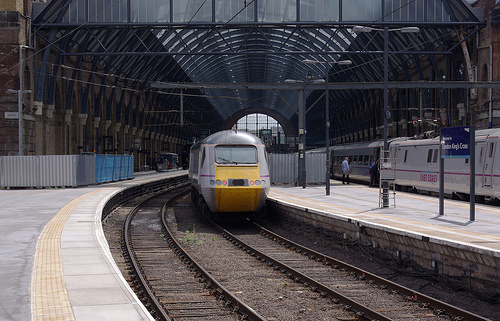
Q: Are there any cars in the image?
A: No, there are no cars.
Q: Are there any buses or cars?
A: No, there are no cars or buses.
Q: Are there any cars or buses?
A: No, there are no cars or buses.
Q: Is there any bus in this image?
A: No, there are no buses.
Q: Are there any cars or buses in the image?
A: No, there are no buses or cars.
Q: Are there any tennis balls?
A: No, there are no tennis balls.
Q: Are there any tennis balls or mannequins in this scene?
A: No, there are no tennis balls or mannequins.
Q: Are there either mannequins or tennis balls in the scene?
A: No, there are no tennis balls or mannequins.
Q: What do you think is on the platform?
A: The cable is on the platform.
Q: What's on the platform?
A: The cable is on the platform.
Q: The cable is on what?
A: The cable is on the platform.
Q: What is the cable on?
A: The cable is on the platform.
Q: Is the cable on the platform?
A: Yes, the cable is on the platform.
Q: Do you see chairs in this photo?
A: No, there are no chairs.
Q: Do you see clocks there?
A: No, there are no clocks.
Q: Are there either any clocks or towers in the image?
A: No, there are no clocks or towers.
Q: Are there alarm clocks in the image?
A: No, there are no alarm clocks.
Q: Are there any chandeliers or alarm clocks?
A: No, there are no alarm clocks or chandeliers.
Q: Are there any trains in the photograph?
A: Yes, there is a train.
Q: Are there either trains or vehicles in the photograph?
A: Yes, there is a train.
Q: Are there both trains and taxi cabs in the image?
A: No, there is a train but no taxis.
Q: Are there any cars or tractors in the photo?
A: No, there are no cars or tractors.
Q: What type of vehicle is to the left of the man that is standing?
A: The vehicle is a train.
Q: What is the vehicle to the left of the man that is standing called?
A: The vehicle is a train.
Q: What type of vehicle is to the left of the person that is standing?
A: The vehicle is a train.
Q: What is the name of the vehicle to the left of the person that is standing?
A: The vehicle is a train.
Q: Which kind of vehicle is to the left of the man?
A: The vehicle is a train.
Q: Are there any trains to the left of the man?
A: Yes, there is a train to the left of the man.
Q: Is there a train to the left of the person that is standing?
A: Yes, there is a train to the left of the man.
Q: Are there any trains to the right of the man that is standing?
A: No, the train is to the left of the man.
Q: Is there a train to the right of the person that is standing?
A: No, the train is to the left of the man.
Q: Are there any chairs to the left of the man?
A: No, there is a train to the left of the man.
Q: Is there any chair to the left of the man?
A: No, there is a train to the left of the man.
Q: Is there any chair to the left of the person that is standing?
A: No, there is a train to the left of the man.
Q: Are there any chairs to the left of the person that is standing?
A: No, there is a train to the left of the man.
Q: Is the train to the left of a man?
A: Yes, the train is to the left of a man.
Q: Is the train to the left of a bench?
A: No, the train is to the left of a man.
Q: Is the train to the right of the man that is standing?
A: No, the train is to the left of the man.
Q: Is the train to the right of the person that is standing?
A: No, the train is to the left of the man.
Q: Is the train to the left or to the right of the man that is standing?
A: The train is to the left of the man.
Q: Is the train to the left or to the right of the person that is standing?
A: The train is to the left of the man.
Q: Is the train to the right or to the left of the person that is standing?
A: The train is to the left of the man.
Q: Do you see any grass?
A: Yes, there is grass.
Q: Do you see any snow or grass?
A: Yes, there is grass.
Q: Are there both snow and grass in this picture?
A: No, there is grass but no snow.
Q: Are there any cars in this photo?
A: No, there are no cars.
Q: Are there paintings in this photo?
A: No, there are no paintings.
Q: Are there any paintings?
A: No, there are no paintings.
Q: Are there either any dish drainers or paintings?
A: No, there are no paintings or dish drainers.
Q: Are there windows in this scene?
A: Yes, there is a window.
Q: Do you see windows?
A: Yes, there is a window.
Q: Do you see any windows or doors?
A: Yes, there is a window.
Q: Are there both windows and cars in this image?
A: No, there is a window but no cars.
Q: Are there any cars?
A: No, there are no cars.